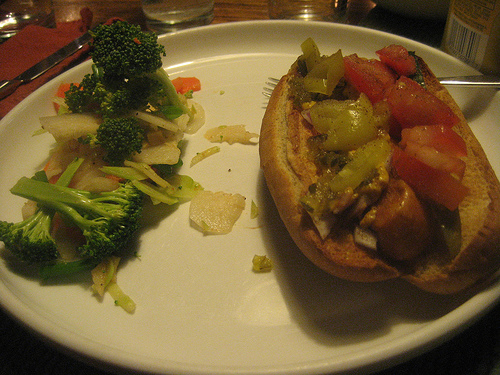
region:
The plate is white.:
[0, 25, 495, 366]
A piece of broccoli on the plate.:
[75, 5, 215, 115]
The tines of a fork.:
[245, 65, 280, 105]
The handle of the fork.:
[425, 40, 495, 95]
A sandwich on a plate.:
[245, 15, 495, 305]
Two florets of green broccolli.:
[0, 156, 161, 276]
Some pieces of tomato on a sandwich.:
[396, 120, 477, 201]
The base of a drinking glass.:
[125, 0, 240, 30]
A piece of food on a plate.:
[176, 166, 252, 261]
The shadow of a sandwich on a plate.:
[259, 225, 431, 350]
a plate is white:
[7, 44, 400, 370]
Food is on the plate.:
[0, 14, 497, 374]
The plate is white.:
[0, 14, 498, 374]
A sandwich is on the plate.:
[256, 35, 498, 302]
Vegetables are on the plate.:
[0, 11, 218, 342]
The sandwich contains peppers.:
[360, 28, 457, 203]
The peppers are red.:
[339, 32, 489, 223]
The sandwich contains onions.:
[287, 33, 397, 219]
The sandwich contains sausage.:
[347, 172, 446, 270]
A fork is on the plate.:
[252, 42, 498, 116]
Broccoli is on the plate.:
[2, 15, 193, 297]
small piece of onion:
[236, 249, 268, 276]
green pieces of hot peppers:
[79, 241, 154, 320]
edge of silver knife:
[25, 28, 98, 65]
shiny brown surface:
[27, 24, 64, 66]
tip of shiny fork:
[253, 64, 280, 99]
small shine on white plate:
[168, 46, 236, 71]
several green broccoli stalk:
[18, 176, 158, 243]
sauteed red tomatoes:
[372, 48, 438, 140]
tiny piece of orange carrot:
[175, 77, 208, 97]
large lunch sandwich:
[270, 33, 490, 311]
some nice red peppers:
[398, 115, 465, 207]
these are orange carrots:
[151, 72, 199, 100]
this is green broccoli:
[10, 165, 163, 264]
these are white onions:
[166, 180, 257, 255]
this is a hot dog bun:
[251, 79, 486, 289]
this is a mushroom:
[366, 171, 435, 253]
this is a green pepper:
[313, 85, 379, 145]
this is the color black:
[13, 334, 30, 359]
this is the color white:
[222, 310, 246, 344]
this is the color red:
[418, 177, 437, 208]